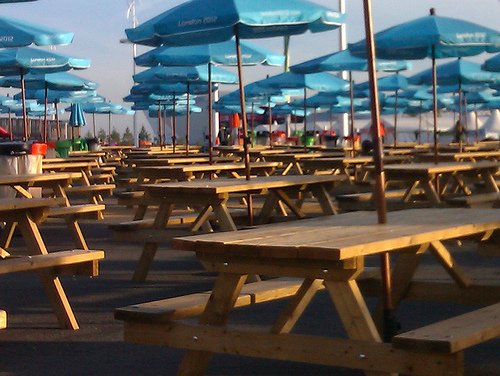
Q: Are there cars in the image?
A: No, there are no cars.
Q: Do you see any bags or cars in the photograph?
A: No, there are no cars or bags.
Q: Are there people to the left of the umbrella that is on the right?
A: Yes, there are people to the left of the umbrella.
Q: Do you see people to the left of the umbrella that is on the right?
A: Yes, there are people to the left of the umbrella.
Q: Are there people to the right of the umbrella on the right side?
A: No, the people are to the left of the umbrella.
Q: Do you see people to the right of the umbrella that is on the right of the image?
A: No, the people are to the left of the umbrella.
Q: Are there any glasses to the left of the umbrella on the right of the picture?
A: No, there are people to the left of the umbrella.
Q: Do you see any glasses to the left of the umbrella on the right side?
A: No, there are people to the left of the umbrella.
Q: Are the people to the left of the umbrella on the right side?
A: Yes, the people are to the left of the umbrella.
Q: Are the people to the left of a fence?
A: No, the people are to the left of the umbrella.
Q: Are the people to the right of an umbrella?
A: No, the people are to the left of an umbrella.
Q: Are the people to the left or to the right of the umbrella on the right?
A: The people are to the left of the umbrella.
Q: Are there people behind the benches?
A: Yes, there are people behind the benches.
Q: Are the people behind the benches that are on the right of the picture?
A: Yes, the people are behind the benches.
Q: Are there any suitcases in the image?
A: No, there are no suitcases.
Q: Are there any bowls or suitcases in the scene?
A: No, there are no suitcases or bowls.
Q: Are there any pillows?
A: No, there are no pillows.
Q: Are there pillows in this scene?
A: No, there are no pillows.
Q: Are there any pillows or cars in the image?
A: No, there are no pillows or cars.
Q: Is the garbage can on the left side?
A: Yes, the garbage can is on the left of the image.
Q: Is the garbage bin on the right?
A: No, the garbage bin is on the left of the image.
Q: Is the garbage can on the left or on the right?
A: The garbage can is on the left of the image.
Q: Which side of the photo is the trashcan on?
A: The trashcan is on the left of the image.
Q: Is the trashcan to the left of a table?
A: Yes, the trashcan is to the left of a table.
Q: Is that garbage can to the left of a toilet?
A: No, the garbage can is to the left of a table.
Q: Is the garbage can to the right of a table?
A: No, the garbage can is to the left of a table.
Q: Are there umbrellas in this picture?
A: Yes, there is an umbrella.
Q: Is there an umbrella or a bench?
A: Yes, there is an umbrella.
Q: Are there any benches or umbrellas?
A: Yes, there is an umbrella.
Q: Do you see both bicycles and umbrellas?
A: No, there is an umbrella but no bicycles.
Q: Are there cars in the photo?
A: No, there are no cars.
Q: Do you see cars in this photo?
A: No, there are no cars.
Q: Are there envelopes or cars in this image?
A: No, there are no cars or envelopes.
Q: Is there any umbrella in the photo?
A: Yes, there is an umbrella.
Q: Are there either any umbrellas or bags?
A: Yes, there is an umbrella.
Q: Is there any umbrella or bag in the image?
A: Yes, there is an umbrella.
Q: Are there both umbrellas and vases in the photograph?
A: No, there is an umbrella but no vases.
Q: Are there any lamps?
A: No, there are no lamps.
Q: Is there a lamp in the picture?
A: No, there are no lamps.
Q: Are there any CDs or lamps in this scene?
A: No, there are no lamps or cds.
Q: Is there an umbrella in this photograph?
A: Yes, there is an umbrella.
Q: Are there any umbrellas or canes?
A: Yes, there is an umbrella.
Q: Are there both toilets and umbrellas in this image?
A: No, there is an umbrella but no toilets.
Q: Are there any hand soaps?
A: No, there are no hand soaps.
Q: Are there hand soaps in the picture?
A: No, there are no hand soaps.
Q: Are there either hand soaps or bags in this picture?
A: No, there are no hand soaps or bags.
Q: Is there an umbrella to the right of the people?
A: Yes, there is an umbrella to the right of the people.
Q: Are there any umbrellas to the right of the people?
A: Yes, there is an umbrella to the right of the people.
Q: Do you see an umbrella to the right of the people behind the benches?
A: Yes, there is an umbrella to the right of the people.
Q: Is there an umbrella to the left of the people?
A: No, the umbrella is to the right of the people.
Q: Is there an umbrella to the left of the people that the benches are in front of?
A: No, the umbrella is to the right of the people.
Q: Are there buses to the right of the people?
A: No, there is an umbrella to the right of the people.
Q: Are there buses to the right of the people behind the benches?
A: No, there is an umbrella to the right of the people.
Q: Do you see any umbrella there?
A: Yes, there is an umbrella.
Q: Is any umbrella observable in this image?
A: Yes, there is an umbrella.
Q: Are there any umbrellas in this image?
A: Yes, there is an umbrella.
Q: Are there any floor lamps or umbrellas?
A: Yes, there is an umbrella.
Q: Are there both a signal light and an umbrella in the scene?
A: No, there is an umbrella but no traffic lights.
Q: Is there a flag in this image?
A: No, there are no flags.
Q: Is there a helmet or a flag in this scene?
A: No, there are no flags or helmets.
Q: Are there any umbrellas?
A: Yes, there is an umbrella.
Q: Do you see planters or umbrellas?
A: Yes, there is an umbrella.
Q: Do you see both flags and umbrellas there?
A: No, there is an umbrella but no flags.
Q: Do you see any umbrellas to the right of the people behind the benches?
A: Yes, there is an umbrella to the right of the people.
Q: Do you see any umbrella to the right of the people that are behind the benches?
A: Yes, there is an umbrella to the right of the people.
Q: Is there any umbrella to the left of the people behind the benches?
A: No, the umbrella is to the right of the people.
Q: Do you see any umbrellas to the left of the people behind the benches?
A: No, the umbrella is to the right of the people.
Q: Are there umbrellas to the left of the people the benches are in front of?
A: No, the umbrella is to the right of the people.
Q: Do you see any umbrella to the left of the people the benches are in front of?
A: No, the umbrella is to the right of the people.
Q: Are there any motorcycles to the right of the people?
A: No, there is an umbrella to the right of the people.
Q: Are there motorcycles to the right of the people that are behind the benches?
A: No, there is an umbrella to the right of the people.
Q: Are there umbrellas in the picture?
A: Yes, there is an umbrella.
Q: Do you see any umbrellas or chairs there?
A: Yes, there is an umbrella.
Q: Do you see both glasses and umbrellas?
A: No, there is an umbrella but no glasses.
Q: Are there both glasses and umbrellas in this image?
A: No, there is an umbrella but no glasses.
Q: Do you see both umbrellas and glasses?
A: No, there is an umbrella but no glasses.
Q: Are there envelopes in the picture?
A: No, there are no envelopes.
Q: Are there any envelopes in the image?
A: No, there are no envelopes.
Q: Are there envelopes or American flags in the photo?
A: No, there are no envelopes or American flags.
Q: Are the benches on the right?
A: Yes, the benches are on the right of the image.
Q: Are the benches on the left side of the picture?
A: No, the benches are on the right of the image.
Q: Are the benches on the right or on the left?
A: The benches are on the right of the image.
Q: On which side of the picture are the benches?
A: The benches are on the right of the image.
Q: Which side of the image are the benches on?
A: The benches are on the right of the image.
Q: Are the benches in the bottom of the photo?
A: Yes, the benches are in the bottom of the image.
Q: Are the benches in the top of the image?
A: No, the benches are in the bottom of the image.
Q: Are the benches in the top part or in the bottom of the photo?
A: The benches are in the bottom of the image.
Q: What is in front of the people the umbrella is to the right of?
A: The benches are in front of the people.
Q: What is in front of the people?
A: The benches are in front of the people.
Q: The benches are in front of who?
A: The benches are in front of the people.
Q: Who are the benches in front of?
A: The benches are in front of the people.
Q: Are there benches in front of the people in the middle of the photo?
A: Yes, there are benches in front of the people.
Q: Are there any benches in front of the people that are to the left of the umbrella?
A: Yes, there are benches in front of the people.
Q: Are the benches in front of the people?
A: Yes, the benches are in front of the people.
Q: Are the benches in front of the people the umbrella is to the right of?
A: Yes, the benches are in front of the people.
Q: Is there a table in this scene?
A: Yes, there is a table.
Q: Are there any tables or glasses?
A: Yes, there is a table.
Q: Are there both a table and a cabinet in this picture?
A: No, there is a table but no cabinets.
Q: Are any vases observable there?
A: No, there are no vases.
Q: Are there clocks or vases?
A: No, there are no vases or clocks.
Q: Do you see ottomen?
A: No, there are no ottomen.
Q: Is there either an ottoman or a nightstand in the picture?
A: No, there are no ottomen or nightstands.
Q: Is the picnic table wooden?
A: Yes, the picnic table is wooden.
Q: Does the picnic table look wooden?
A: Yes, the picnic table is wooden.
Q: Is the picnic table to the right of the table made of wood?
A: Yes, the picnic table is made of wood.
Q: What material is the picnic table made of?
A: The picnic table is made of wood.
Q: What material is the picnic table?
A: The picnic table is made of wood.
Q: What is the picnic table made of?
A: The picnic table is made of wood.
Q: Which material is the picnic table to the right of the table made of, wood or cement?
A: The picnic table is made of wood.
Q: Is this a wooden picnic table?
A: Yes, this is a wooden picnic table.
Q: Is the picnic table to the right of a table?
A: Yes, the picnic table is to the right of a table.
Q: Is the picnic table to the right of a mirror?
A: No, the picnic table is to the right of a table.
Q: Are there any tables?
A: Yes, there is a table.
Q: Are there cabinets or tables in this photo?
A: Yes, there is a table.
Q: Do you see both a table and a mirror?
A: No, there is a table but no mirrors.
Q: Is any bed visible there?
A: No, there are no beds.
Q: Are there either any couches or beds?
A: No, there are no beds or couches.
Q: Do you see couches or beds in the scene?
A: No, there are no beds or couches.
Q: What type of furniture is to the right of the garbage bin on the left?
A: The piece of furniture is a table.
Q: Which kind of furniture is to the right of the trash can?
A: The piece of furniture is a table.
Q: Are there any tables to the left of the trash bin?
A: No, the table is to the right of the trash bin.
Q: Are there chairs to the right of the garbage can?
A: No, there is a table to the right of the garbage can.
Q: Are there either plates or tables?
A: Yes, there is a table.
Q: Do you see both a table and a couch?
A: No, there is a table but no couches.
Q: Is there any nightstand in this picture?
A: No, there are no nightstands.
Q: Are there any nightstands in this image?
A: No, there are no nightstands.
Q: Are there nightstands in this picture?
A: No, there are no nightstands.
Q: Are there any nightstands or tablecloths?
A: No, there are no nightstands or tablecloths.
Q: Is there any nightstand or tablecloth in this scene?
A: No, there are no nightstands or tablecloths.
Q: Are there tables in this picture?
A: Yes, there is a table.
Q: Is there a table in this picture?
A: Yes, there is a table.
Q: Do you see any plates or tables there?
A: Yes, there is a table.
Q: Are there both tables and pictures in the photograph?
A: No, there is a table but no pictures.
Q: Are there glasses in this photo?
A: No, there are no glasses.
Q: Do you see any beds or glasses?
A: No, there are no glasses or beds.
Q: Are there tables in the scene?
A: Yes, there is a table.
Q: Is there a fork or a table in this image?
A: Yes, there is a table.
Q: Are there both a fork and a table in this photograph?
A: No, there is a table but no forks.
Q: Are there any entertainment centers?
A: No, there are no entertainment centers.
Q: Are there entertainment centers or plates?
A: No, there are no entertainment centers or plates.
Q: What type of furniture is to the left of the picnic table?
A: The piece of furniture is a table.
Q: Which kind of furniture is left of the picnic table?
A: The piece of furniture is a table.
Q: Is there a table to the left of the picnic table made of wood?
A: Yes, there is a table to the left of the picnic table.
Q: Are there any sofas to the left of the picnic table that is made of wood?
A: No, there is a table to the left of the picnic table.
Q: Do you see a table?
A: Yes, there is a table.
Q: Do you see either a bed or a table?
A: Yes, there is a table.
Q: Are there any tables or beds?
A: Yes, there is a table.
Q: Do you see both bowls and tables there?
A: No, there is a table but no bowls.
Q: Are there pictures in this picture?
A: No, there are no pictures.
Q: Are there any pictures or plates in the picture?
A: No, there are no pictures or plates.